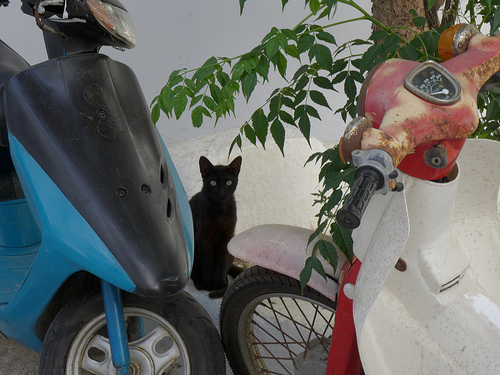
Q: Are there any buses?
A: No, there are no buses.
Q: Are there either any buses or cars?
A: No, there are no buses or cars.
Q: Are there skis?
A: No, there are no skis.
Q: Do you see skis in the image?
A: No, there are no skis.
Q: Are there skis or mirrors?
A: No, there are no skis or mirrors.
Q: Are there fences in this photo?
A: No, there are no fences.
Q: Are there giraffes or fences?
A: No, there are no fences or giraffes.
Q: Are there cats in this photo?
A: Yes, there is a cat.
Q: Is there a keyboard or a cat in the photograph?
A: Yes, there is a cat.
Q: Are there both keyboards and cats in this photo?
A: No, there is a cat but no keyboards.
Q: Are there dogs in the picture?
A: No, there are no dogs.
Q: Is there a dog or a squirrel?
A: No, there are no dogs or squirrels.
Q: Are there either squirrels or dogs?
A: No, there are no dogs or squirrels.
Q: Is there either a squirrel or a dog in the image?
A: No, there are no dogs or squirrels.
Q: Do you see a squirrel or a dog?
A: No, there are no dogs or squirrels.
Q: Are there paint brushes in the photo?
A: No, there are no paint brushes.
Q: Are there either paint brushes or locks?
A: No, there are no paint brushes or locks.